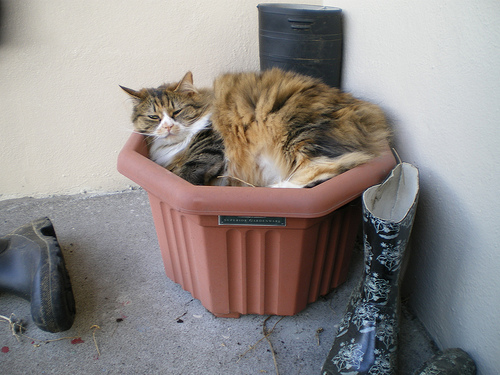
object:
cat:
[117, 69, 397, 188]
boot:
[315, 164, 416, 375]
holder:
[122, 70, 396, 317]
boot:
[0, 217, 76, 335]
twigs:
[236, 316, 342, 375]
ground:
[4, 190, 497, 370]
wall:
[3, 0, 499, 337]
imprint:
[218, 214, 292, 230]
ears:
[117, 86, 146, 100]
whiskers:
[121, 125, 160, 138]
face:
[129, 90, 205, 139]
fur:
[223, 76, 371, 175]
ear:
[176, 71, 196, 90]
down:
[136, 145, 389, 217]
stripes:
[145, 90, 178, 108]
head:
[116, 70, 212, 140]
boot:
[254, 2, 347, 87]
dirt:
[15, 292, 437, 375]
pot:
[115, 128, 399, 316]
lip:
[120, 149, 399, 220]